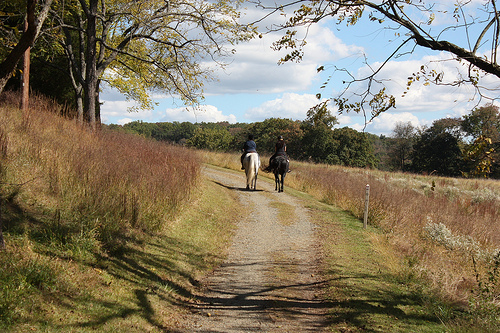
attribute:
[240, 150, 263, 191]
horse — walking, white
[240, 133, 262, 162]
person — wearing blue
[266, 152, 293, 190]
horse — black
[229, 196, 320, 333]
trail — dirt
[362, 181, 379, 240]
pole — white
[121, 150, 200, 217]
bush — brown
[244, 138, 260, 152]
shirt — blue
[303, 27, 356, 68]
cloud — puffy, white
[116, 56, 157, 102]
leaves — green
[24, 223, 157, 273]
grass — tall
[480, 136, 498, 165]
leaves — yellow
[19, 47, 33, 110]
bark — brown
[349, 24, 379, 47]
sky — blue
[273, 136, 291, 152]
man — wearing black